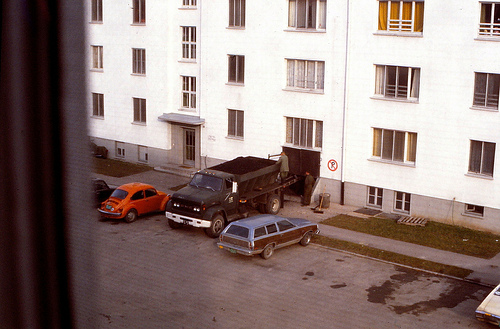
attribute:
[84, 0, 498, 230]
building — white, part, large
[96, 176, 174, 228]
car — red, beatle, orange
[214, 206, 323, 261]
car — blue, brown, station wagon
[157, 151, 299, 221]
truck — black, large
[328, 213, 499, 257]
grass — grassy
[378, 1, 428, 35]
curtains — orange, orage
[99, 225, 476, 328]
floor — paved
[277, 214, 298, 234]
window — part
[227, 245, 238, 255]
license plate — green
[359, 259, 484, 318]
mark — large